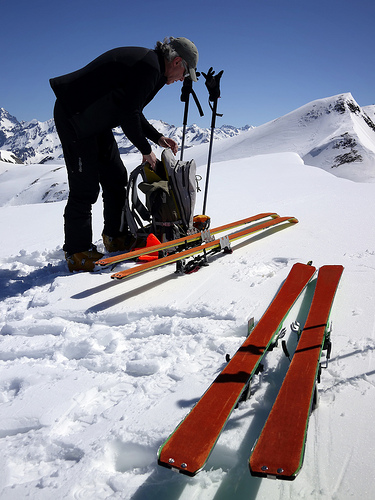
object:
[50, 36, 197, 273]
man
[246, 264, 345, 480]
ski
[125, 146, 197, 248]
backpack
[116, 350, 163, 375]
footprint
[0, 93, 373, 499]
snow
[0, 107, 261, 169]
mountain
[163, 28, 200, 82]
hat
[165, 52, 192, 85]
face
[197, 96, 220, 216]
pole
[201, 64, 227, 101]
glove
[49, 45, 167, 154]
jacket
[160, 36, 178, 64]
hair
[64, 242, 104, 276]
boot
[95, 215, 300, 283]
ski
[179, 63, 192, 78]
sunglasses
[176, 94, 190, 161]
pole